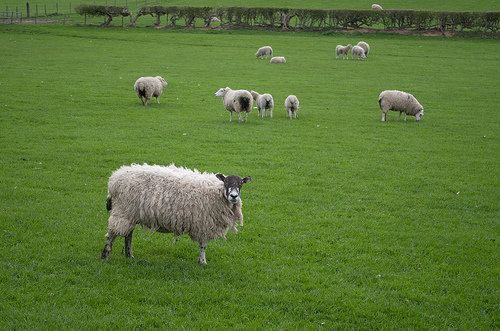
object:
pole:
[24, 1, 30, 16]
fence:
[0, 0, 149, 26]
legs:
[194, 235, 211, 262]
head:
[210, 170, 252, 205]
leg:
[101, 217, 123, 256]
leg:
[119, 225, 134, 256]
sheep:
[334, 42, 356, 61]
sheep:
[99, 162, 251, 262]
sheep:
[254, 45, 274, 59]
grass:
[0, 0, 499, 330]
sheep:
[282, 94, 302, 120]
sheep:
[250, 89, 274, 118]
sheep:
[214, 85, 253, 125]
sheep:
[376, 88, 425, 123]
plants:
[72, 3, 134, 29]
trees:
[73, 1, 498, 46]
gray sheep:
[132, 75, 167, 108]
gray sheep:
[93, 162, 250, 268]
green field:
[1, 1, 498, 330]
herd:
[94, 41, 425, 267]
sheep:
[267, 55, 286, 67]